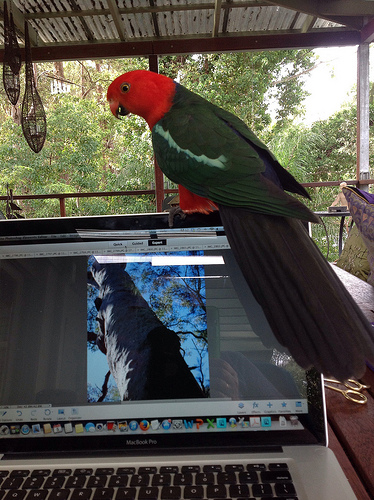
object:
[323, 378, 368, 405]
scissor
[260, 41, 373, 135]
sky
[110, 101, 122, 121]
beak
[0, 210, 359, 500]
laptop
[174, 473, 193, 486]
buttons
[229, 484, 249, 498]
button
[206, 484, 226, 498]
button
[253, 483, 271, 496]
button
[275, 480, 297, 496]
button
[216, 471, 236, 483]
button